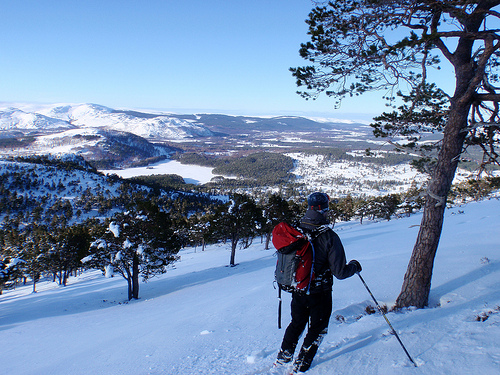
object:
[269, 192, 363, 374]
man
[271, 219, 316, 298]
backpack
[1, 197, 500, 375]
slope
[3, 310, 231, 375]
snow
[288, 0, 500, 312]
tree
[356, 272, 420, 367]
ski pole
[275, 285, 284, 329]
strap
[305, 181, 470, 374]
stand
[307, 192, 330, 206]
helmet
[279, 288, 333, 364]
pants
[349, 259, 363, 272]
gloves